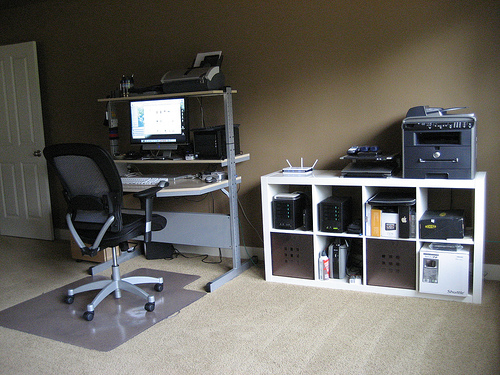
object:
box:
[365, 239, 414, 291]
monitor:
[130, 98, 186, 142]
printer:
[160, 51, 228, 96]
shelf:
[266, 274, 472, 302]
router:
[279, 155, 317, 176]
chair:
[42, 143, 170, 322]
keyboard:
[117, 176, 171, 186]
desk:
[88, 85, 258, 295]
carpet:
[0, 236, 499, 374]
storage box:
[268, 231, 315, 281]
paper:
[417, 209, 467, 240]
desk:
[259, 169, 489, 304]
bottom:
[90, 244, 262, 294]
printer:
[398, 103, 480, 181]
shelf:
[269, 227, 474, 247]